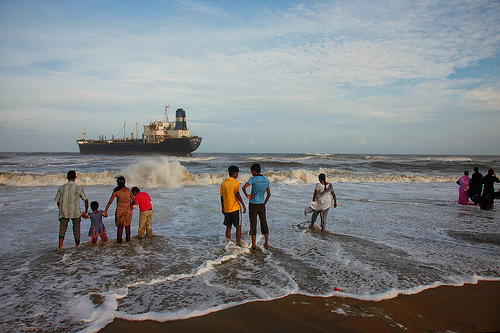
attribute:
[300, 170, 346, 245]
woman water — standing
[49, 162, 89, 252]
man — standing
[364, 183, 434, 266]
ocean — wavy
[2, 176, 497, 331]
shore — edge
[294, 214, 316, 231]
net — fishing net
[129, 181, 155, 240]
shirt — red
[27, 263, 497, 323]
shore — part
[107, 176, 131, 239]
woman — standing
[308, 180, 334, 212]
shirt — white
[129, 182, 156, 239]
child — looking down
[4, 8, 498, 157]
sky — overcast